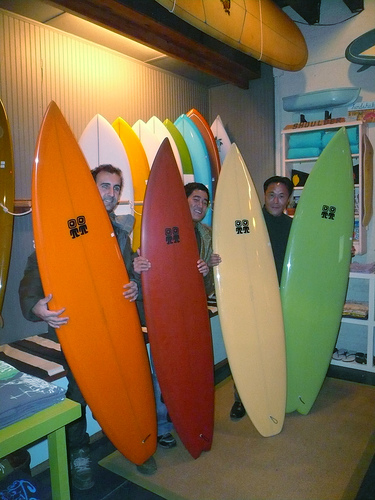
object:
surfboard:
[31, 99, 158, 465]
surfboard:
[139, 134, 216, 460]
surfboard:
[212, 141, 287, 438]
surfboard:
[280, 125, 354, 416]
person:
[19, 164, 158, 491]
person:
[133, 182, 214, 449]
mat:
[95, 375, 374, 498]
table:
[0, 361, 82, 500]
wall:
[0, 8, 216, 196]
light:
[40, 8, 165, 96]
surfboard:
[78, 113, 135, 242]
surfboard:
[110, 115, 150, 249]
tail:
[191, 434, 212, 460]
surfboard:
[157, 0, 308, 73]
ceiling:
[269, 0, 373, 25]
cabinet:
[0, 284, 227, 483]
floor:
[122, 411, 373, 499]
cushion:
[0, 295, 218, 383]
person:
[209, 176, 356, 420]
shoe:
[342, 350, 356, 362]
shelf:
[330, 273, 375, 371]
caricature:
[66, 218, 80, 240]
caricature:
[76, 214, 88, 237]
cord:
[0, 204, 32, 218]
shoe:
[332, 349, 347, 360]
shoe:
[355, 352, 367, 365]